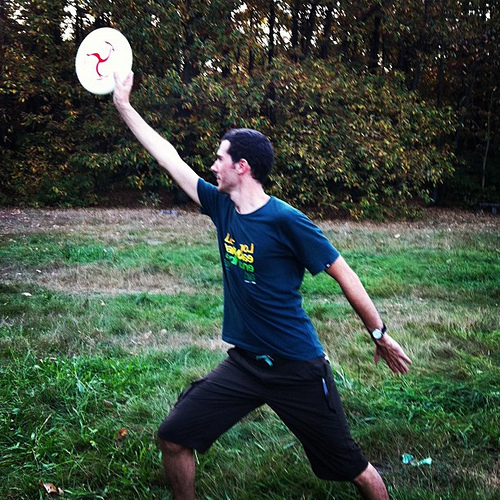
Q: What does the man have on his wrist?
A: Watch.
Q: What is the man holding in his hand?
A: Frisbee.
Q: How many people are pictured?
A: 1.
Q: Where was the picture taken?
A: Park.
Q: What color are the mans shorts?
A: Brown.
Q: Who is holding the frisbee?
A: Man.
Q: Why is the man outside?
A: Playing.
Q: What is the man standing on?
A: Grass.